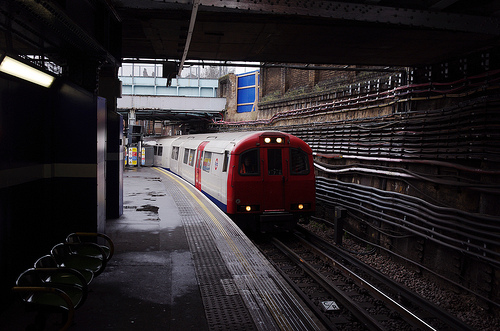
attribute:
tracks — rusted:
[257, 218, 499, 329]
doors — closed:
[195, 148, 205, 183]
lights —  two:
[262, 137, 282, 145]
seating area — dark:
[1, 220, 125, 322]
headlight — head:
[241, 200, 265, 218]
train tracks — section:
[253, 216, 442, 328]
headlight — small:
[297, 200, 305, 210]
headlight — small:
[241, 202, 252, 212]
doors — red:
[190, 137, 205, 188]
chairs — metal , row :
[5, 224, 120, 324]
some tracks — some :
[275, 238, 395, 313]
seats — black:
[36, 233, 86, 295]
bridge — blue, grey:
[118, 57, 226, 112]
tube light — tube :
[1, 52, 54, 89]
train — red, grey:
[138, 132, 319, 232]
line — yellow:
[152, 165, 244, 260]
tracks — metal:
[299, 250, 380, 315]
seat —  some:
[63, 227, 118, 268]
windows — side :
[181, 147, 199, 168]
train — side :
[124, 123, 319, 234]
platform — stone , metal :
[131, 197, 211, 322]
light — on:
[276, 133, 284, 145]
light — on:
[260, 134, 271, 144]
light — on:
[296, 200, 306, 210]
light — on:
[244, 199, 255, 212]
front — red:
[226, 130, 321, 223]